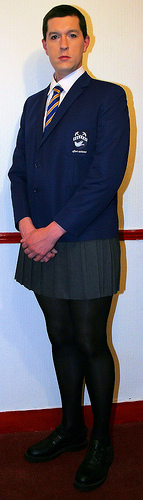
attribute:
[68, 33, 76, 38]
eye — RED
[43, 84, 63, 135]
tie — BLUE, GOLD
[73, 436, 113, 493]
shoe — BLACK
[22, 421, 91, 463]
shoe — BLACK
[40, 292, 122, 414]
pantyhose — BLACK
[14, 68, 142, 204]
blazer — BLUE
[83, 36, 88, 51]
ear — on the left